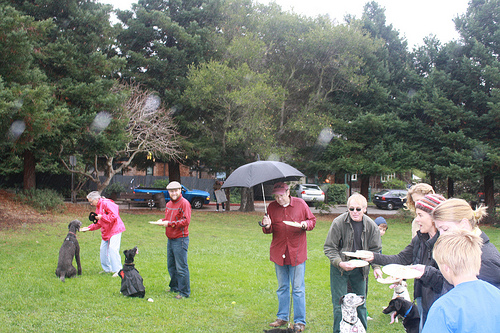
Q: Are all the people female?
A: No, they are both male and female.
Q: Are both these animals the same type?
A: Yes, all the animals are dogs.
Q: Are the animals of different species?
A: No, all the animals are dogs.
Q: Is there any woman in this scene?
A: Yes, there is a woman.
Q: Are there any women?
A: Yes, there is a woman.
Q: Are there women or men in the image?
A: Yes, there is a woman.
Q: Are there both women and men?
A: Yes, there are both a woman and a man.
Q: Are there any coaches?
A: No, there are no coaches.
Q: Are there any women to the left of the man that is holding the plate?
A: Yes, there is a woman to the left of the man.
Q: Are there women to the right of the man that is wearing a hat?
A: No, the woman is to the left of the man.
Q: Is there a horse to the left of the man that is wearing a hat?
A: No, there is a woman to the left of the man.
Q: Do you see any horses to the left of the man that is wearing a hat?
A: No, there is a woman to the left of the man.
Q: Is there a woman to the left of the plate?
A: Yes, there is a woman to the left of the plate.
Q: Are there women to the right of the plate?
A: No, the woman is to the left of the plate.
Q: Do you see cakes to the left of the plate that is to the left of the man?
A: No, there is a woman to the left of the plate.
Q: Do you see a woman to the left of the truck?
A: Yes, there is a woman to the left of the truck.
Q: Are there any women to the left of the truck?
A: Yes, there is a woman to the left of the truck.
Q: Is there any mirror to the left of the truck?
A: No, there is a woman to the left of the truck.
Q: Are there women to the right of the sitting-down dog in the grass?
A: Yes, there is a woman to the right of the dog.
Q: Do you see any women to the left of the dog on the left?
A: No, the woman is to the right of the dog.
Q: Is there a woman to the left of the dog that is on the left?
A: No, the woman is to the right of the dog.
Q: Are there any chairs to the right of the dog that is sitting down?
A: No, there is a woman to the right of the dog.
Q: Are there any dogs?
A: Yes, there is a dog.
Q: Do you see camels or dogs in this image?
A: Yes, there is a dog.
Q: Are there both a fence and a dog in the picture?
A: No, there is a dog but no fences.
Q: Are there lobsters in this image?
A: No, there are no lobsters.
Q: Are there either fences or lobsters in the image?
A: No, there are no lobsters or fences.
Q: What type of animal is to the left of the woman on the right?
A: The animal is a dog.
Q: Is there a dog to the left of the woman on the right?
A: Yes, there is a dog to the left of the woman.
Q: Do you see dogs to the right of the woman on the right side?
A: No, the dog is to the left of the woman.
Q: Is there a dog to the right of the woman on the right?
A: No, the dog is to the left of the woman.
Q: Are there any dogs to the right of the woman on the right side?
A: No, the dog is to the left of the woman.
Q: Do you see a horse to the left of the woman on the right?
A: No, there is a dog to the left of the woman.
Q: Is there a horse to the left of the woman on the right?
A: No, there is a dog to the left of the woman.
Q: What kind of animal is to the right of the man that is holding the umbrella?
A: The animal is a dog.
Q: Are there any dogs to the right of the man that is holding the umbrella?
A: Yes, there is a dog to the right of the man.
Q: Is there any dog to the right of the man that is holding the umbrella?
A: Yes, there is a dog to the right of the man.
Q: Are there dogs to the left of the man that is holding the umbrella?
A: No, the dog is to the right of the man.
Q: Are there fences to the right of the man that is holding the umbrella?
A: No, there is a dog to the right of the man.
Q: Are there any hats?
A: Yes, there is a hat.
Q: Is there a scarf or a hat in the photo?
A: Yes, there is a hat.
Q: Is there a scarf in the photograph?
A: No, there are no scarves.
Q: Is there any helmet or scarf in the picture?
A: No, there are no scarves or helmets.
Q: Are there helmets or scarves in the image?
A: No, there are no scarves or helmets.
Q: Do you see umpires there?
A: No, there are no umpires.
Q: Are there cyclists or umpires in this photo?
A: No, there are no umpires or cyclists.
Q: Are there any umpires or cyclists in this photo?
A: No, there are no umpires or cyclists.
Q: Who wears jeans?
A: The man wears jeans.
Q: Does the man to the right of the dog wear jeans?
A: Yes, the man wears jeans.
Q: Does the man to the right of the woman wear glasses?
A: No, the man wears jeans.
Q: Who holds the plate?
A: The man holds the plate.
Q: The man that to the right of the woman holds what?
A: The man holds the plate.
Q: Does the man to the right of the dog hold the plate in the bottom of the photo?
A: Yes, the man holds the plate.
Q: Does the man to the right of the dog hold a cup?
A: No, the man holds the plate.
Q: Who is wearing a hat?
A: The man is wearing a hat.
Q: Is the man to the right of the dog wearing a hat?
A: Yes, the man is wearing a hat.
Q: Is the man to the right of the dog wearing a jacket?
A: No, the man is wearing a hat.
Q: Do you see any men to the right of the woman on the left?
A: Yes, there is a man to the right of the woman.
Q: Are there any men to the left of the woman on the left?
A: No, the man is to the right of the woman.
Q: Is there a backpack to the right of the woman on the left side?
A: No, there is a man to the right of the woman.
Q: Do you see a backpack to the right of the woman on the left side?
A: No, there is a man to the right of the woman.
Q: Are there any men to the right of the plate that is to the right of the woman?
A: Yes, there is a man to the right of the plate.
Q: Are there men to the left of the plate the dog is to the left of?
A: No, the man is to the right of the plate.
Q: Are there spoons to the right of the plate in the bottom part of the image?
A: No, there is a man to the right of the plate.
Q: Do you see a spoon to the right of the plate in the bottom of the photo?
A: No, there is a man to the right of the plate.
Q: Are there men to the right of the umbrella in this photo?
A: No, the man is to the left of the umbrella.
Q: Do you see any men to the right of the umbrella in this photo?
A: No, the man is to the left of the umbrella.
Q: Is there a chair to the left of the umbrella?
A: No, there is a man to the left of the umbrella.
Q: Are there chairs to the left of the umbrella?
A: No, there is a man to the left of the umbrella.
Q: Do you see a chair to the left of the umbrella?
A: No, there is a man to the left of the umbrella.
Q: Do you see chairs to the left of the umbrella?
A: No, there is a man to the left of the umbrella.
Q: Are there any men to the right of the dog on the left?
A: Yes, there is a man to the right of the dog.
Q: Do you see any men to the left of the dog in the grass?
A: No, the man is to the right of the dog.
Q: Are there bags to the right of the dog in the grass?
A: No, there is a man to the right of the dog.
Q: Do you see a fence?
A: No, there are no fences.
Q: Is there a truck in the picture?
A: Yes, there is a truck.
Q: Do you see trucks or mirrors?
A: Yes, there is a truck.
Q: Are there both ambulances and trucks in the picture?
A: No, there is a truck but no ambulances.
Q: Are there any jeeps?
A: No, there are no jeeps.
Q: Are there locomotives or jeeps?
A: No, there are no jeeps or locomotives.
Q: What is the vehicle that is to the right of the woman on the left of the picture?
A: The vehicle is a truck.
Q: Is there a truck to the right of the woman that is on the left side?
A: Yes, there is a truck to the right of the woman.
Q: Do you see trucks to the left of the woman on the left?
A: No, the truck is to the right of the woman.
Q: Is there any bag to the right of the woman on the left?
A: No, there is a truck to the right of the woman.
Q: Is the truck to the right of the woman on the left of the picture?
A: Yes, the truck is to the right of the woman.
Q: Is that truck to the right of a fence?
A: No, the truck is to the right of the woman.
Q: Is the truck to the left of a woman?
A: No, the truck is to the right of a woman.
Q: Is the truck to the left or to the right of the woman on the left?
A: The truck is to the right of the woman.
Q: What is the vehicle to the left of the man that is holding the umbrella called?
A: The vehicle is a truck.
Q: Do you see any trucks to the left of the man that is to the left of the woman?
A: Yes, there is a truck to the left of the man.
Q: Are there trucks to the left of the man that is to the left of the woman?
A: Yes, there is a truck to the left of the man.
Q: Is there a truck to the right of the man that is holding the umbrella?
A: No, the truck is to the left of the man.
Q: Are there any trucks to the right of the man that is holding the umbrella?
A: No, the truck is to the left of the man.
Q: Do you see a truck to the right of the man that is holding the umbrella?
A: No, the truck is to the left of the man.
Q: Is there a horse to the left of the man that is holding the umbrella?
A: No, there is a truck to the left of the man.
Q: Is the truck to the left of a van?
A: No, the truck is to the left of a man.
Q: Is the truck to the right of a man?
A: No, the truck is to the left of a man.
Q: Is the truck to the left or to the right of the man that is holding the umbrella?
A: The truck is to the left of the man.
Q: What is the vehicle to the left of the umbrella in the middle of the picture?
A: The vehicle is a truck.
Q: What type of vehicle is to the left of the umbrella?
A: The vehicle is a truck.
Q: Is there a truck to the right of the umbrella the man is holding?
A: No, the truck is to the left of the umbrella.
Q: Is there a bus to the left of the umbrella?
A: No, there is a truck to the left of the umbrella.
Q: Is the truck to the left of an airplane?
A: No, the truck is to the left of the umbrella.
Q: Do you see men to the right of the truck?
A: Yes, there is a man to the right of the truck.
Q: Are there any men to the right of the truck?
A: Yes, there is a man to the right of the truck.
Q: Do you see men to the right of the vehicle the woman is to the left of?
A: Yes, there is a man to the right of the truck.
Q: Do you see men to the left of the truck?
A: No, the man is to the right of the truck.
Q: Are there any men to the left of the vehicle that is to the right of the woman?
A: No, the man is to the right of the truck.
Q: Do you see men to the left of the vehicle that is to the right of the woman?
A: No, the man is to the right of the truck.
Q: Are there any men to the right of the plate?
A: Yes, there is a man to the right of the plate.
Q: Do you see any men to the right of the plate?
A: Yes, there is a man to the right of the plate.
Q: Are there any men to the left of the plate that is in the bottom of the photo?
A: No, the man is to the right of the plate.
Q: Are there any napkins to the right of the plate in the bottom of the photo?
A: No, there is a man to the right of the plate.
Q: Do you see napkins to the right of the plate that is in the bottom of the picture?
A: No, there is a man to the right of the plate.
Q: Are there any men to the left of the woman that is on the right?
A: Yes, there is a man to the left of the woman.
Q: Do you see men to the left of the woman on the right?
A: Yes, there is a man to the left of the woman.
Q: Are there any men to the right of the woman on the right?
A: No, the man is to the left of the woman.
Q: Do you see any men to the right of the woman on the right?
A: No, the man is to the left of the woman.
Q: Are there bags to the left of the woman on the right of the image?
A: No, there is a man to the left of the woman.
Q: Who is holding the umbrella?
A: The man is holding the umbrella.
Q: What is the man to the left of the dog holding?
A: The man is holding the umbrella.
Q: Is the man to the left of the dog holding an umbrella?
A: Yes, the man is holding an umbrella.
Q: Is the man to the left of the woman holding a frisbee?
A: No, the man is holding an umbrella.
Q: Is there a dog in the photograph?
A: Yes, there is a dog.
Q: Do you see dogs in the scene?
A: Yes, there is a dog.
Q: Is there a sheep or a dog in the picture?
A: Yes, there is a dog.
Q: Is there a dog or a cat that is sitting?
A: Yes, the dog is sitting.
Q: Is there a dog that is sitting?
A: Yes, there is a dog that is sitting.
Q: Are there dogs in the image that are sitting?
A: Yes, there is a dog that is sitting.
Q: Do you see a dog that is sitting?
A: Yes, there is a dog that is sitting.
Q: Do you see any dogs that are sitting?
A: Yes, there is a dog that is sitting.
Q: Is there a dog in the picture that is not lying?
A: Yes, there is a dog that is sitting.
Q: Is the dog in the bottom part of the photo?
A: Yes, the dog is in the bottom of the image.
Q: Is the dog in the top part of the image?
A: No, the dog is in the bottom of the image.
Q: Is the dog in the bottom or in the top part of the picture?
A: The dog is in the bottom of the image.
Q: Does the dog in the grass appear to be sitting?
A: Yes, the dog is sitting.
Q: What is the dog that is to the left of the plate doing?
A: The dog is sitting.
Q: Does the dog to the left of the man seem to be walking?
A: No, the dog is sitting.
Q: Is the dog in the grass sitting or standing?
A: The dog is sitting.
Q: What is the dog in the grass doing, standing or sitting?
A: The dog is sitting.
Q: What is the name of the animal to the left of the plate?
A: The animal is a dog.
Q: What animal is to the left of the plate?
A: The animal is a dog.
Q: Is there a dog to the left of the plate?
A: Yes, there is a dog to the left of the plate.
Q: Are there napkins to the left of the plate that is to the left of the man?
A: No, there is a dog to the left of the plate.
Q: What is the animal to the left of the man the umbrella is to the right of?
A: The animal is a dog.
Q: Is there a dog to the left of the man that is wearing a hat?
A: Yes, there is a dog to the left of the man.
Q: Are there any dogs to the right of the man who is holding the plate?
A: No, the dog is to the left of the man.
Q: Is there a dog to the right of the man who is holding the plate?
A: No, the dog is to the left of the man.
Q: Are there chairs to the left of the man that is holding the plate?
A: No, there is a dog to the left of the man.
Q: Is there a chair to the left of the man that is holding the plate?
A: No, there is a dog to the left of the man.